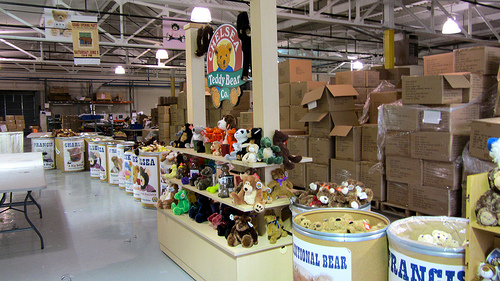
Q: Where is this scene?
A: Warehouse.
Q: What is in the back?
A: Boxes.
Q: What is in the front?
A: Teddy bears.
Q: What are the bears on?
A: Shelves.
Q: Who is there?
A: No one.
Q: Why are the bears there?
A: Storage.